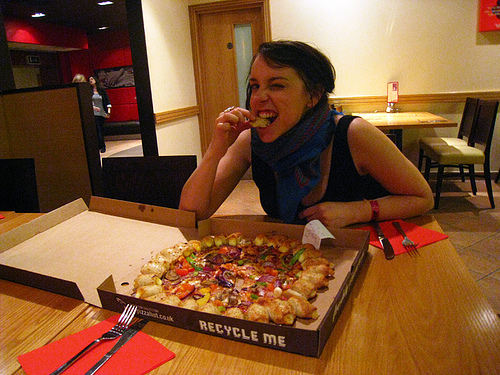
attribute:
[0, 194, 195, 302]
lid — open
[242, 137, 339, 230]
scarf — blue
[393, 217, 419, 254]
fork — silver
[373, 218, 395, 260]
knife — silver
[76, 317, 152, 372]
knife — silver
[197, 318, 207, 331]
letter — white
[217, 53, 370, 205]
woman — eating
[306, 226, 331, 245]
receipt — paper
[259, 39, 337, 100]
hair — black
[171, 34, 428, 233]
woman — eating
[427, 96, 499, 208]
chair — white, black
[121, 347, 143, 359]
napkin — red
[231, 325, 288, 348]
letter — white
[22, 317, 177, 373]
napkin — red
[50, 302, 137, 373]
fork — silver, long, gray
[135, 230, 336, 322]
pizza — full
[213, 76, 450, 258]
chairs — empty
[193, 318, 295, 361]
letter — white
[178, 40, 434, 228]
woman — eating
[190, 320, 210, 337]
letter — white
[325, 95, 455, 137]
table — brown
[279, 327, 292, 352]
letter — white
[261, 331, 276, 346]
letter — white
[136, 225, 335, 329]
pizza — boxed, large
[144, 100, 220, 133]
trim — wall